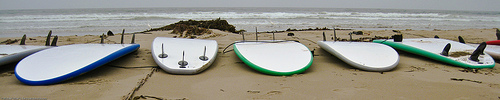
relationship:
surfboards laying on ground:
[3, 34, 499, 86] [1, 34, 498, 100]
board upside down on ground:
[152, 34, 220, 72] [1, 34, 498, 100]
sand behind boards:
[1, 34, 498, 100] [3, 34, 499, 86]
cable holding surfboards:
[117, 62, 161, 99] [3, 34, 499, 86]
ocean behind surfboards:
[0, 3, 499, 30] [3, 34, 499, 86]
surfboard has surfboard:
[378, 29, 496, 73] [370, 37, 496, 69]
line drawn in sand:
[409, 60, 427, 76] [1, 34, 498, 100]